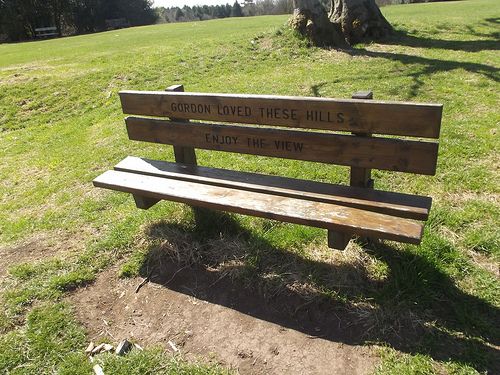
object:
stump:
[292, 1, 402, 50]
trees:
[230, 0, 240, 17]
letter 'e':
[286, 140, 295, 151]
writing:
[167, 101, 345, 151]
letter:
[222, 105, 229, 116]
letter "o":
[198, 103, 204, 113]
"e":
[274, 108, 284, 118]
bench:
[92, 83, 441, 251]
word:
[171, 101, 211, 113]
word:
[215, 106, 251, 118]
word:
[256, 106, 298, 120]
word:
[203, 132, 238, 144]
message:
[170, 103, 344, 154]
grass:
[57, 52, 160, 83]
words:
[305, 111, 345, 123]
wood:
[352, 105, 397, 130]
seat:
[92, 153, 434, 249]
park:
[0, 0, 499, 374]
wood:
[92, 84, 443, 251]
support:
[324, 88, 377, 250]